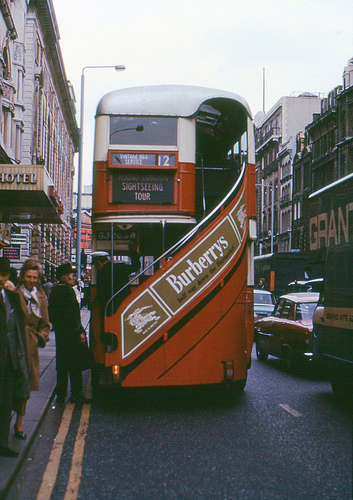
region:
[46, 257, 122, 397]
man standing beside the bus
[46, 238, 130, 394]
man standing beside the bus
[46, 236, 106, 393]
man standing beside the bus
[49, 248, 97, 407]
man standing beside the bus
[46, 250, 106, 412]
man standing beside the bus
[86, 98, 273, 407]
this is a bus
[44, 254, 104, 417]
this is a person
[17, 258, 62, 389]
this is a person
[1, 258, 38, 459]
this is a person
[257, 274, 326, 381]
this is a car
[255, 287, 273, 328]
this is a car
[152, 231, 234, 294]
a word on the bus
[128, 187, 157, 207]
a word on the bus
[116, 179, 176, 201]
a word on the bus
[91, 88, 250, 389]
sightseeing tour bus on street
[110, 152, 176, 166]
route and bus number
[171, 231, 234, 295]
name of tour bus company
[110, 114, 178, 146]
window on top of bus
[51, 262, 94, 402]
passenger waiting to get on bus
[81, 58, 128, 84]
top of street light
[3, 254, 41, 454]
people on the street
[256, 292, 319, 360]
car next to bus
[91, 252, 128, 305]
the tour bus driver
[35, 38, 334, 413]
this is a double decker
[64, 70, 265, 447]
the bus is tall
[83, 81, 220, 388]
the bus is white and red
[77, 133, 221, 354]
this is a city bus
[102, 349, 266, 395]
the tail lights are red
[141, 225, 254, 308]
the ad is brown and white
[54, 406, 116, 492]
the lines are yellow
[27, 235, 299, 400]
this is a city street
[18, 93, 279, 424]
this is an urban area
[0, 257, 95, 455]
People standing on the side of the road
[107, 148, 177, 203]
Sign on front of tour bus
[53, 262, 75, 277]
Black hat on man's head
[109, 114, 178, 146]
Window on front of tour bus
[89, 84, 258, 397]
Red tour bus parked in the road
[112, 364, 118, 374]
Light near bottom of tour bus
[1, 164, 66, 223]
Sign on front of hotel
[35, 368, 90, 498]
Yellow double line on side of road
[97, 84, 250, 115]
White curved roof on tour bus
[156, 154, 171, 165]
the number on the bus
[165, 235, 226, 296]
he word burberrys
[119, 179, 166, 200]
it is for a sightseeing tour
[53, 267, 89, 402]
the man about to get on the bus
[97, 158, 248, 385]
steps going to the top level of the bus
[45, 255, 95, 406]
a man wearing a black hat and coat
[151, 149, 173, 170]
the white numbers of the bus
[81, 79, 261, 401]
a double-decker bus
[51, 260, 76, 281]
black hat on the man beside the bus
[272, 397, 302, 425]
white stripe painted on the street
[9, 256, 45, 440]
a woman wearing a brown coat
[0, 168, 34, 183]
a hotel sign on an awning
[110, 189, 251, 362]
a diagonal advertisement on the front of the bus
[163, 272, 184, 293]
A letter on a sign.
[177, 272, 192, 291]
A letter on a sign.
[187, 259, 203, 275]
A letter on a sign.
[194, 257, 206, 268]
A letter on a sign.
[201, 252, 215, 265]
A letter on a sign.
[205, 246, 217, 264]
A letter on a sign.